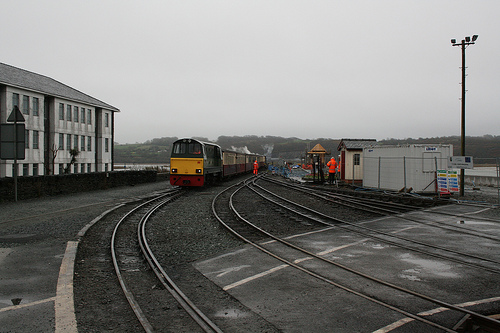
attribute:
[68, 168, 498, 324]
tracks — multiple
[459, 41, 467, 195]
pole — tall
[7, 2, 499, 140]
sky — gray, overcast, above, gra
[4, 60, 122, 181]
building — white, three story, to the left, small, multi=stor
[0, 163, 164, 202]
fence — chain link, running, running between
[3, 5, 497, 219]
background — black, white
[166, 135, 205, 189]
front — yellow, red, black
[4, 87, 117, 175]
windows — multiple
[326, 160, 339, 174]
jacket — orange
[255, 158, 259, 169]
jacket — orange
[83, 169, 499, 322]
sets — tracks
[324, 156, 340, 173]
top — orange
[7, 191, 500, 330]
crossing area — here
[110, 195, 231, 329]
pair — tracks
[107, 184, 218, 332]
tracks — metal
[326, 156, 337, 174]
coat — orange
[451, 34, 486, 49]
set — street lights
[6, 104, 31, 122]
street sign — triangular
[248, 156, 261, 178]
worker — standing out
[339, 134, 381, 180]
shed — small